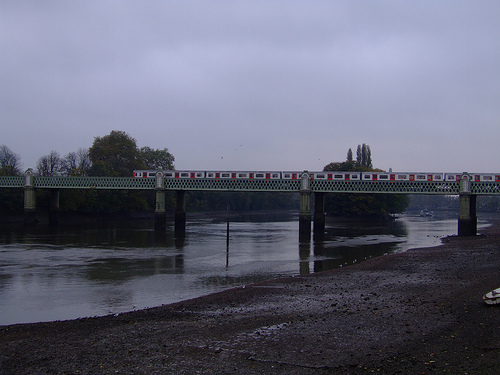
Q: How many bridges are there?
A: One.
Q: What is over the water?
A: A bridge.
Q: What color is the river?
A: Black and gray.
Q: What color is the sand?
A: Brown.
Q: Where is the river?
A: Under the bridge.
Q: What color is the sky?
A: Gray.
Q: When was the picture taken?
A: Daytime.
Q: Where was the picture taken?
A: Over a bridge.